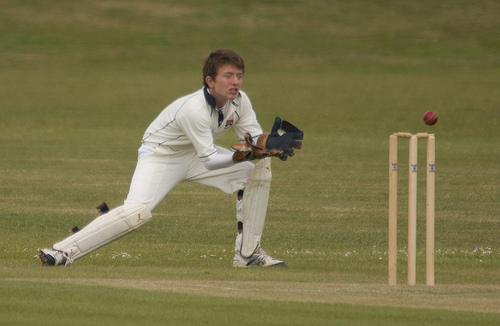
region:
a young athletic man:
[11, 24, 475, 311]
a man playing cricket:
[31, 20, 497, 322]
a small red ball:
[414, 103, 447, 128]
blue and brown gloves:
[236, 117, 316, 166]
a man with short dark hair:
[186, 37, 281, 107]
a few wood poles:
[370, 107, 461, 300]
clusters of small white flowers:
[448, 244, 497, 258]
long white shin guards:
[45, 191, 157, 261]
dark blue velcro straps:
[87, 198, 117, 215]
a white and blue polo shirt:
[127, 77, 264, 167]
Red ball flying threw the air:
[408, 69, 464, 161]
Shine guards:
[36, 201, 253, 317]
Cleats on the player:
[13, 229, 96, 289]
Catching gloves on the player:
[257, 56, 295, 189]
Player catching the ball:
[212, 47, 499, 217]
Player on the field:
[28, 39, 350, 324]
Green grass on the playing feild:
[298, 194, 394, 321]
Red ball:
[397, 100, 447, 152]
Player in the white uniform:
[128, 39, 325, 246]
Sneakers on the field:
[203, 175, 319, 317]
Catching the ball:
[198, 84, 464, 164]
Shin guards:
[41, 197, 172, 324]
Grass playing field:
[341, 106, 388, 271]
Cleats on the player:
[26, 243, 98, 308]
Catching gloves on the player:
[195, 102, 370, 196]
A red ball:
[388, 105, 454, 132]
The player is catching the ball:
[78, 53, 302, 240]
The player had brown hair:
[38, 39, 347, 259]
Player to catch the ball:
[194, 12, 311, 171]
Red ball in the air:
[384, 87, 441, 149]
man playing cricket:
[29, 40, 457, 279]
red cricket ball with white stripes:
[405, 98, 459, 142]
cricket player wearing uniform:
[32, 18, 357, 291]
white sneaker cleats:
[29, 228, 81, 278]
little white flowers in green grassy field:
[118, 238, 232, 265]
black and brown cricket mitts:
[217, 107, 314, 176]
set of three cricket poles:
[365, 107, 473, 295]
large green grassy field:
[322, 28, 467, 103]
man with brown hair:
[185, 36, 255, 114]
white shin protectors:
[235, 154, 288, 263]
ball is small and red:
[418, 103, 443, 126]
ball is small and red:
[421, 100, 451, 132]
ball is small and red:
[415, 100, 468, 147]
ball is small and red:
[410, 90, 445, 133]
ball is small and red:
[427, 109, 440, 126]